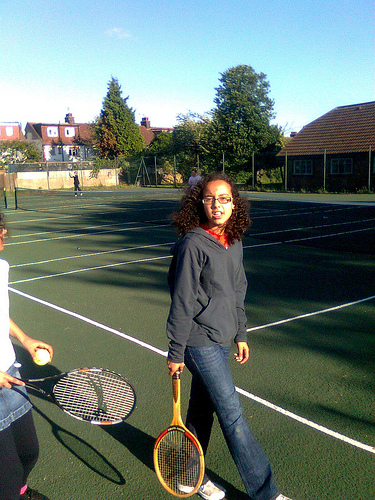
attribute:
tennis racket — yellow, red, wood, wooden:
[151, 374, 204, 500]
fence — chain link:
[3, 147, 369, 200]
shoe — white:
[186, 480, 226, 497]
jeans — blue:
[171, 345, 279, 494]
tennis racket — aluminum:
[21, 367, 134, 425]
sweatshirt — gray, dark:
[158, 234, 251, 357]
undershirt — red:
[202, 230, 232, 249]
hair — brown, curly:
[172, 191, 251, 240]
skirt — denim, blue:
[0, 368, 36, 432]